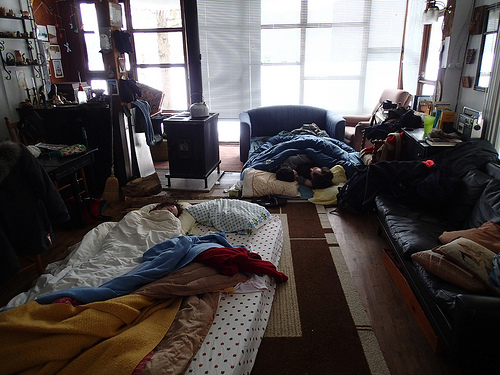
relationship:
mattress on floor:
[0, 200, 285, 374] [0, 143, 498, 374]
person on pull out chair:
[273, 153, 311, 183] [241, 104, 347, 204]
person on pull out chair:
[305, 149, 353, 196] [241, 104, 347, 204]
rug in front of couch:
[178, 198, 387, 374] [375, 172, 499, 360]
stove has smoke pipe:
[162, 111, 222, 191] [179, 1, 205, 105]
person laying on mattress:
[149, 201, 183, 219] [0, 200, 285, 374]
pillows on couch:
[409, 221, 500, 295] [375, 172, 499, 360]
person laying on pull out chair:
[273, 153, 311, 183] [241, 104, 347, 204]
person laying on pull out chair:
[305, 149, 353, 196] [241, 104, 347, 204]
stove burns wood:
[162, 111, 222, 191] [123, 174, 163, 200]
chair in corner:
[343, 89, 415, 151] [341, 4, 499, 161]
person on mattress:
[149, 201, 183, 219] [0, 200, 285, 374]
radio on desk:
[455, 106, 484, 140] [400, 127, 464, 157]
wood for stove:
[123, 174, 163, 200] [162, 111, 222, 191]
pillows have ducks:
[409, 221, 500, 295] [454, 242, 498, 278]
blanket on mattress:
[34, 233, 247, 306] [0, 200, 285, 374]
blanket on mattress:
[0, 293, 182, 374] [0, 200, 285, 374]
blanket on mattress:
[195, 248, 289, 285] [0, 200, 285, 374]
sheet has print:
[186, 215, 284, 375] [223, 309, 230, 315]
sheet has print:
[186, 215, 284, 375] [233, 316, 240, 325]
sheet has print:
[186, 215, 284, 375] [205, 358, 214, 366]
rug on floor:
[178, 198, 387, 374] [0, 143, 498, 374]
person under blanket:
[273, 153, 311, 183] [236, 131, 361, 182]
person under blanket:
[305, 149, 353, 196] [236, 131, 361, 182]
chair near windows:
[343, 89, 415, 151] [261, 1, 427, 118]